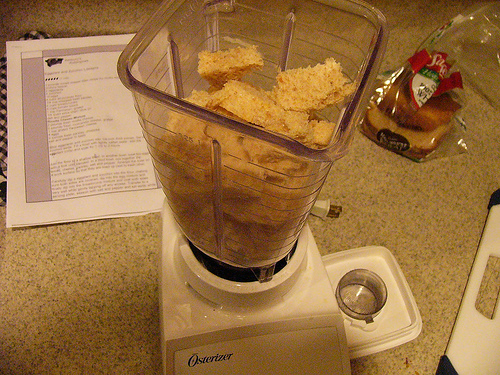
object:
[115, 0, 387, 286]
jar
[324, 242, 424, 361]
top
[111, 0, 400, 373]
blender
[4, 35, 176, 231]
sheet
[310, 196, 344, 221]
plug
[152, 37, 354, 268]
bread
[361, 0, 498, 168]
bag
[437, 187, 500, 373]
board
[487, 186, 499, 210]
corner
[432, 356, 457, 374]
corner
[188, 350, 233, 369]
logo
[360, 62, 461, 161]
bread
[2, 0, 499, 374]
counter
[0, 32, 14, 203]
cloth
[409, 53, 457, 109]
writing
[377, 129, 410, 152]
writing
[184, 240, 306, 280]
ring